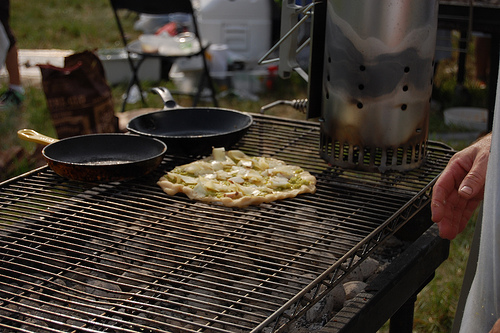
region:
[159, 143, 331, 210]
The dough on the gril.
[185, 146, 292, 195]
The square pieces of chicken on the dough on the grill.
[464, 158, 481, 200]
The person's thumb on the right.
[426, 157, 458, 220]
The index finger of the person on the right.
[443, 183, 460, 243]
The middle finger of the person on the right.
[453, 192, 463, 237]
The ring finger of the person on the right.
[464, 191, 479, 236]
The pinky finger of the person on the right.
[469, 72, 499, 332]
The gray shirt the person is wearing on the right.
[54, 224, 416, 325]
The charcoal in the grill.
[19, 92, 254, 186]
The two frying pans on the grill.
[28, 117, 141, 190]
frying pan with tan handle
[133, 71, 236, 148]
black frying pan on grill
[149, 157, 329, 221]
pie with vegetables on grill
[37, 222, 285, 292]
dirty grill top with coals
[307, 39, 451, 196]
small silver furnace with burn marks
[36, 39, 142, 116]
black bag of coal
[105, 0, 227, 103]
black foldable picnic chair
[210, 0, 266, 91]
white cooler in the distance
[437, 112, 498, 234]
man's hand near grill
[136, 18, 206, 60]
tupperware on the black chair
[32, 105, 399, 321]
the metal grill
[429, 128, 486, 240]
a man's right hand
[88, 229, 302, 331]
charcoal in the grill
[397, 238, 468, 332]
the green grass on the ground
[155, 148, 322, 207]
the food on the grill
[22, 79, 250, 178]
the two black frying pans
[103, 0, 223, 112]
the folding chair in the back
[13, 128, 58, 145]
the light colored pan handle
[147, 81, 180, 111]
the dark colored pan handle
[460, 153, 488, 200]
the thumb on the hand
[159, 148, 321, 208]
dish cooking over coals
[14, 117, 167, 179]
The pan is on the grill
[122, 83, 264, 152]
the pan is on the grill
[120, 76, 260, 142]
the pan is black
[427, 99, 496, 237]
a hand behind the grill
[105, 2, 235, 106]
a chair behind the grill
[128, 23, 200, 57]
containers are on the chair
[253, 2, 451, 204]
something metal on the grill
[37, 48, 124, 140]
a paper bag is behind the grill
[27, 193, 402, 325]
coals under the grill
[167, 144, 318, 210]
food cooking on grill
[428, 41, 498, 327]
person standing beside grill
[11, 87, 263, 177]
frying pans on grill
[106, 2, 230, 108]
black folding chair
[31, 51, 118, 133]
bag of charcoal in background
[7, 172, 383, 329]
charcoal underneath grill grate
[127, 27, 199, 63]
stuff sitting on folding chair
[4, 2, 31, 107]
leg of person in background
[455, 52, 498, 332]
shirt of person standing at grill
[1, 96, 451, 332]
grate on top of grill